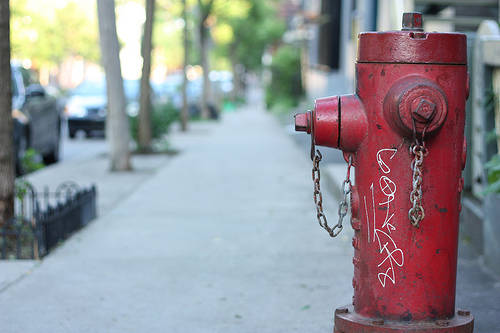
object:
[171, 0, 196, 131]
tree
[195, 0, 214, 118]
tree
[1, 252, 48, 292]
crack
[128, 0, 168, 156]
tree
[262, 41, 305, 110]
bush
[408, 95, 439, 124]
bolt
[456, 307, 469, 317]
bolt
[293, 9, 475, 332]
fire hydrant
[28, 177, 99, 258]
fence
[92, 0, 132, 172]
tree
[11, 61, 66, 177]
car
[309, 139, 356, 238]
chain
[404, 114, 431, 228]
chain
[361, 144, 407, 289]
graffiti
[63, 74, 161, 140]
car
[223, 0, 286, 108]
tree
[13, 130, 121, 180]
parking space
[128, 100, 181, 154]
bush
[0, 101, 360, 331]
sidewalk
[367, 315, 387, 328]
bolt